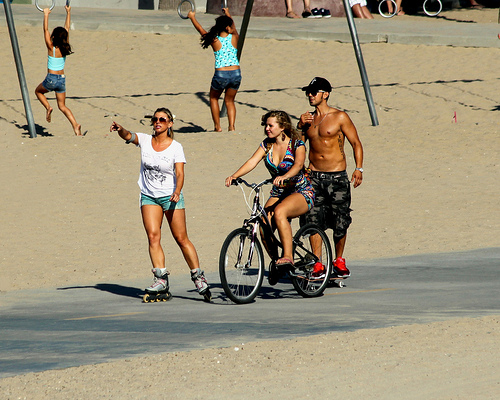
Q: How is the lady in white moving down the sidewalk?
A: On skates.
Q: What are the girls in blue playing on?
A: Swing set.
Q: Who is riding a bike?
A: A young woman.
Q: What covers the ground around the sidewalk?
A: Sand.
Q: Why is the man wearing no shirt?
A: To show off.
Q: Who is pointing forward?
A: The woman in white.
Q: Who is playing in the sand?
A: Two girls.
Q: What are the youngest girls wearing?
A: Blue tank tops and denim shorts.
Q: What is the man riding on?
A: Skateboard.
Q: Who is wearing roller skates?
A: The woman in white.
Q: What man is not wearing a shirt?
A: The man in the black hat.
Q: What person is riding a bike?
A: Thw woman with the brightly colored outfit.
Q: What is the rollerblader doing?
A: Pointing her right hand.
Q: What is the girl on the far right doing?
A: Hanging from metal rings.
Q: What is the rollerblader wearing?
A: Blue shorts and a white shirt.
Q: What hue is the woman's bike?
A: Black.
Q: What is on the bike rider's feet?
A: Flip flops.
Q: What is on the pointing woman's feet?
A: Roller blades.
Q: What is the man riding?
A: A skateboard.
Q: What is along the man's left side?
A: A tattoo.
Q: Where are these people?
A: The beach.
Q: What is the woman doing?
A: Riding a bike.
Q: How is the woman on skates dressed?
A: In shorts.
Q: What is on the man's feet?
A: Sneakers.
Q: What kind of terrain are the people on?
A: Sand.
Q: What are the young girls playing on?
A: Jungle gym.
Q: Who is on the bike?
A: A woman on a bicycle.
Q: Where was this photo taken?
A: Outside at the park.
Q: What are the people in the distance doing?
A: Playing on the monkey bars.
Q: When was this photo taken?
A: During the day.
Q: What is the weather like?
A: Sunny and warm.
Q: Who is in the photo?
A: People at the park.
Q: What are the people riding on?
A: A path.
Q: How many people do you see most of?
A: 5.